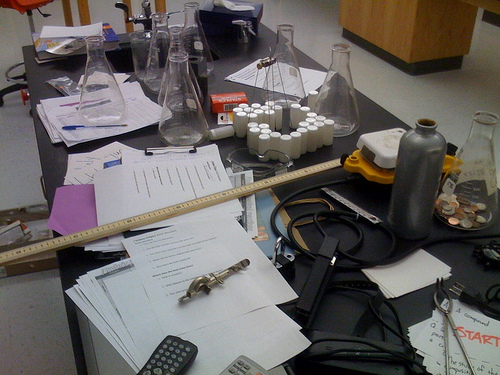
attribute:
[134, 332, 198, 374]
calculator — black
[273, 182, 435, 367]
cords — black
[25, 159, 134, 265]
paper — purple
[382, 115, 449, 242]
bottle — grey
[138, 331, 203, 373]
remote — black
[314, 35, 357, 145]
jar — glass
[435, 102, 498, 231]
jar — glass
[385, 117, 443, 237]
jar — glass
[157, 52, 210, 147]
jar — glass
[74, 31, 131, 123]
jar — glass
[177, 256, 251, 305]
tool — metal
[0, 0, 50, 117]
chair — black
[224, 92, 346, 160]
bottles — small, white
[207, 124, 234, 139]
bottle — small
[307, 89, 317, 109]
bottle — small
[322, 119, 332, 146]
bottle — small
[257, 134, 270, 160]
bottle — small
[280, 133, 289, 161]
bottle — small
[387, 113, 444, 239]
container — silver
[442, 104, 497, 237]
container — glass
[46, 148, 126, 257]
paper — purple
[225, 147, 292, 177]
glasses — safety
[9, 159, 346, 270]
ruler — beige, wooden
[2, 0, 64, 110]
chair — red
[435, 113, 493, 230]
jar — glass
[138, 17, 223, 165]
beaker — clear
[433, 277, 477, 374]
tongs — hot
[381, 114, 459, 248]
bottle — metal